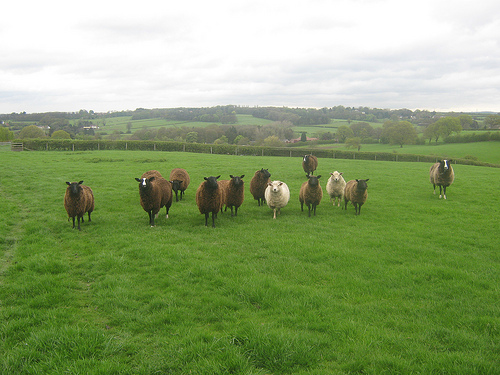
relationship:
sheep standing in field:
[62, 180, 96, 228] [8, 129, 498, 369]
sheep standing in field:
[138, 165, 195, 227] [8, 129, 498, 369]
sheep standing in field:
[216, 173, 245, 217] [8, 129, 498, 369]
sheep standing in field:
[168, 166, 191, 201] [8, 129, 498, 369]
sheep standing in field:
[428, 156, 455, 198] [8, 129, 498, 369]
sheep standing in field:
[134, 170, 172, 228] [31, 227, 455, 349]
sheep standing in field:
[62, 179, 96, 231] [31, 227, 455, 349]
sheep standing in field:
[168, 166, 191, 201] [31, 227, 455, 349]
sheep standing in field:
[216, 173, 245, 217] [31, 227, 455, 349]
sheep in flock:
[250, 167, 272, 207] [131, 152, 371, 227]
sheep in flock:
[134, 170, 172, 228] [131, 152, 371, 227]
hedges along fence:
[54, 112, 251, 157] [6, 136, 498, 168]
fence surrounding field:
[11, 137, 492, 173] [10, 147, 488, 355]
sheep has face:
[131, 171, 177, 230] [139, 175, 148, 186]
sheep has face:
[256, 174, 300, 214] [205, 174, 221, 194]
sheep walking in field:
[194, 175, 226, 228] [8, 129, 498, 369]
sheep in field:
[168, 166, 191, 201] [8, 129, 498, 369]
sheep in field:
[216, 173, 245, 217] [8, 129, 498, 369]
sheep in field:
[194, 175, 226, 228] [8, 129, 498, 369]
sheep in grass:
[246, 165, 271, 207] [4, 152, 498, 371]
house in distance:
[26, 120, 103, 141] [9, 99, 485, 159]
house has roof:
[262, 119, 346, 151] [291, 135, 319, 141]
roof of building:
[79, 124, 100, 128] [77, 117, 108, 144]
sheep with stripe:
[428, 158, 455, 198] [445, 155, 450, 168]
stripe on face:
[445, 155, 450, 168] [436, 155, 455, 175]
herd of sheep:
[56, 167, 476, 216] [43, 134, 404, 226]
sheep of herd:
[265, 180, 291, 220] [56, 167, 476, 216]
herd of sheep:
[56, 167, 476, 216] [355, 157, 361, 208]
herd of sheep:
[56, 167, 476, 216] [323, 163, 346, 207]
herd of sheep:
[56, 167, 476, 216] [249, 172, 283, 213]